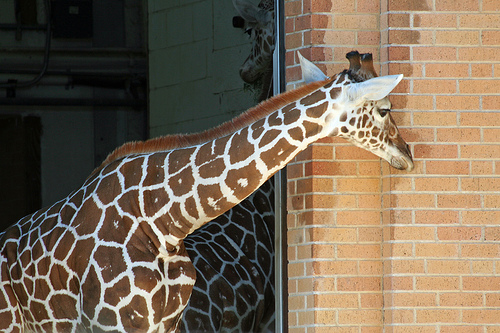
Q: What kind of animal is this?
A: Giraffe.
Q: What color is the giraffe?
A: Brown and white.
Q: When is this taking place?
A: Daytime.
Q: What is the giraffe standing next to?
A: Brick wall.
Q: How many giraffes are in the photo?
A: Two.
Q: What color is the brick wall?
A: Light red.